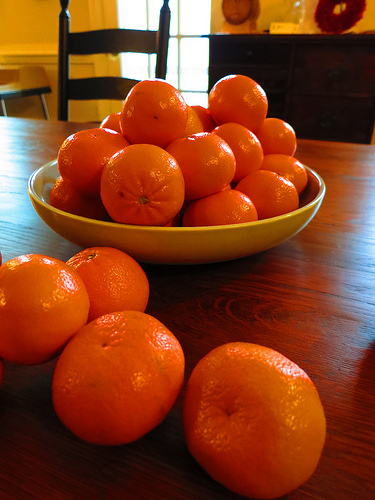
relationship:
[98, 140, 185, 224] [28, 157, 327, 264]
fruit on bowl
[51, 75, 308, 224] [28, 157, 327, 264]
fruit on bowl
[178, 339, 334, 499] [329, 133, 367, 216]
fruit on table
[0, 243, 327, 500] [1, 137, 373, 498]
orange on table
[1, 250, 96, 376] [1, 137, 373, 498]
orange on table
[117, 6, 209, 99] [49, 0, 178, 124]
window behind chair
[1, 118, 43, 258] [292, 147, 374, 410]
light reflecting on table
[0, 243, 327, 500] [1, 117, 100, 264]
orange on table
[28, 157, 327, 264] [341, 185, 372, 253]
bowl on table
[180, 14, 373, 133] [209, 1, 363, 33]
chest against wall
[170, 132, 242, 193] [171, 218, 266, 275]
orange stacked bowl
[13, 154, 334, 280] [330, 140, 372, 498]
bowl on table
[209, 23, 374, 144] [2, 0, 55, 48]
cabinet against wall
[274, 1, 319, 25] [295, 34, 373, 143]
glass on cabinet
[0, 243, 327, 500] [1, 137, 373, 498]
orange lying on table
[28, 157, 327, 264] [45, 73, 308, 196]
bowl holding oranges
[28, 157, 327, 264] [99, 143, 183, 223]
bowl of tangerine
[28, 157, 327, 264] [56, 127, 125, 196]
bowl of tangerine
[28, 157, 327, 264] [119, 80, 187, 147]
bowl of tangerine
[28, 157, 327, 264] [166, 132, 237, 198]
bowl of tangerine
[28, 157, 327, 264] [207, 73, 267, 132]
bowl of tangerine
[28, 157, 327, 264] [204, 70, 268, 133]
bowl holds tangerine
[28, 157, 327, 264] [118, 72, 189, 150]
bowl holds tangerine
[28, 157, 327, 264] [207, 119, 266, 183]
bowl holds tangerine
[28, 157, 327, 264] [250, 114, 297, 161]
bowl holds tangerine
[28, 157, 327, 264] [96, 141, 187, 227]
bowl holds tangerine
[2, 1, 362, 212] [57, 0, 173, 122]
room has chair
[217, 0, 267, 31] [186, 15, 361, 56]
barrel on buffet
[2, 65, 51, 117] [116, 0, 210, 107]
table by window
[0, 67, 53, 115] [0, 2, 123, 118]
table by wall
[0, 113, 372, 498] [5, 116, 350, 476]
chair by table